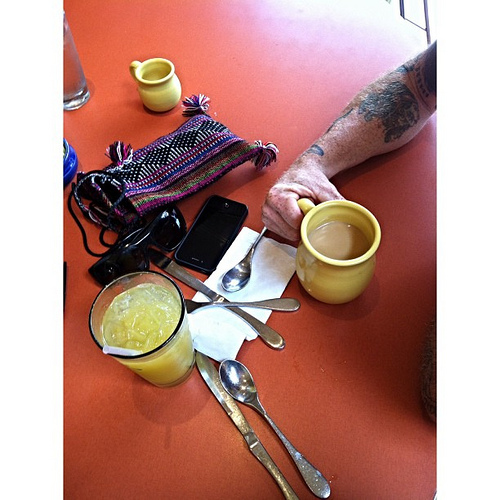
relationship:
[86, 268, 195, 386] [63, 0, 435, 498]
glass on table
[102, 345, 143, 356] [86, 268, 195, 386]
straw with glass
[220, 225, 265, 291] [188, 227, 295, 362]
spoon on napkin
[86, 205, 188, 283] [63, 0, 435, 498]
sunglasses on table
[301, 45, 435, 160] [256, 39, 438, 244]
tatto on arm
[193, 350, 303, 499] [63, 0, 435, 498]
knife on table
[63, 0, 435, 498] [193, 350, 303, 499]
table under knife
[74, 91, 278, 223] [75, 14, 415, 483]
bag on table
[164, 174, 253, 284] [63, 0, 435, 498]
phone sitting on a table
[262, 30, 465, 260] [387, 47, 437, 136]
man has elbow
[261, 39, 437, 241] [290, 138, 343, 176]
man has wrist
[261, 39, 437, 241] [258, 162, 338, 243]
man has hand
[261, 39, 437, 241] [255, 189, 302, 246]
man has fingers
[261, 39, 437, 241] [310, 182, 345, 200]
man has thumb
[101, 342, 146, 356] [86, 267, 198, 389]
straw on cup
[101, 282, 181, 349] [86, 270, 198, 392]
ice floating on top of drink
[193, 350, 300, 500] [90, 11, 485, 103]
knife laying on a table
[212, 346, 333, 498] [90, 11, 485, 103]
spoon laying on a table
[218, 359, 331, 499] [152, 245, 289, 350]
spoon crossing a knife